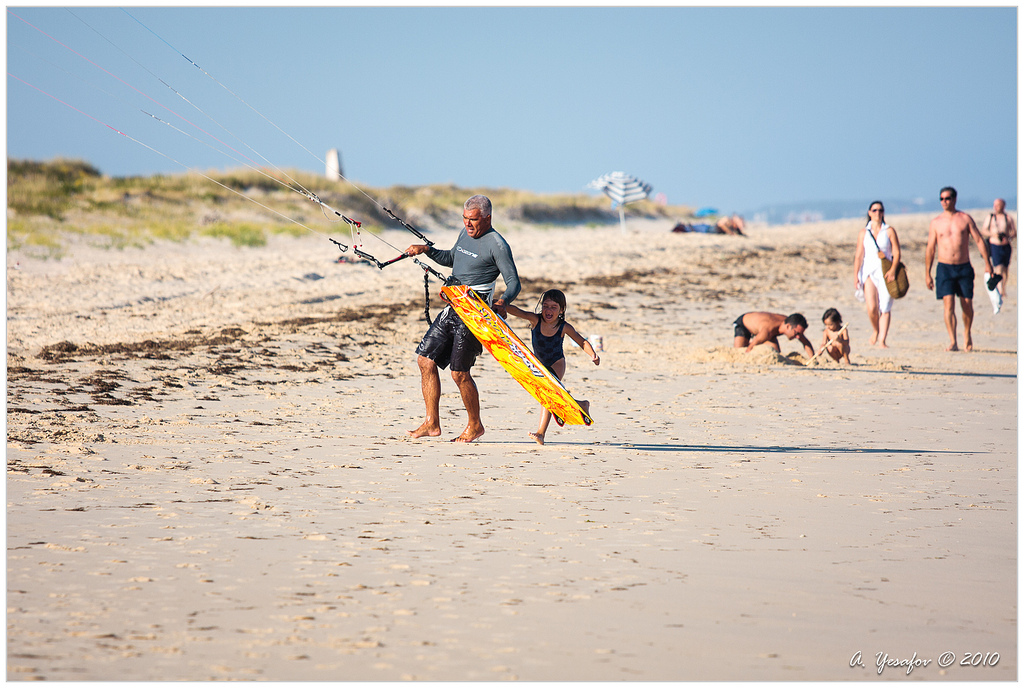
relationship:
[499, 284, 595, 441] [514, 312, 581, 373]
girl wearing swimsuit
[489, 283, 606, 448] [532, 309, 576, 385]
girl wearing swimsuit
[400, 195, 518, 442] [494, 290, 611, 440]
man with girl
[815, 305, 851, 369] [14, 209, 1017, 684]
girl playing in sand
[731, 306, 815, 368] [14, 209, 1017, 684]
man playing in sand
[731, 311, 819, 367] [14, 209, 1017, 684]
man in sand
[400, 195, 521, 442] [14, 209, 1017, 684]
man in sand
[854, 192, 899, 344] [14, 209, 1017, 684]
people in sand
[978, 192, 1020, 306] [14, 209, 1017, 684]
people in sand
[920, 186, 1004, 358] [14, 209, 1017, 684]
people in sand